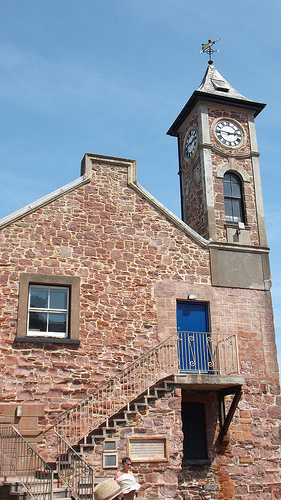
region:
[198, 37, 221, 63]
a lightning rod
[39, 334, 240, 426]
a metal structure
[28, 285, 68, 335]
a white crystal window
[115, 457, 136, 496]
a short hair woman on the scene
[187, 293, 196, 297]
a lamp at the top of the door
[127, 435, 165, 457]
an illegible sign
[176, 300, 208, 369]
a crystal door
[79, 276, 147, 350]
rustic brick wall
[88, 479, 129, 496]
a cream color hat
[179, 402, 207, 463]
a closed window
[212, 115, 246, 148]
clock on the side of the tower.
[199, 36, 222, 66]
Weather vein on the roof.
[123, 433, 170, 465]
Sign on the side of the building.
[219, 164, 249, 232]
window on the building.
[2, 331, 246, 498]
Stairs on the building.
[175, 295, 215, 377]
blue door on the building.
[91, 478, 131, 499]
Tan hat in the forefront.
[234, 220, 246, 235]
Security camera on the window.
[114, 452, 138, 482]
Woman standing by the building.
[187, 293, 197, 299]
Light above the door.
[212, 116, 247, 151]
White and black clock.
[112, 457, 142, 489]
Woman wearing black sunglasses.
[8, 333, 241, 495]
Staircase going up side of building.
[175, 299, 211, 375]
Blue door on side of building.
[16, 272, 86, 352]
Window on side of building.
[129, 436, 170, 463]
Plaque on side of building.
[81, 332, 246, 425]
Metal rail along stairs.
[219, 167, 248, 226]
Window that is rounded on top.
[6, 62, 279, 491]
Red brick historical building.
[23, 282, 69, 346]
Reflection of a tree in window.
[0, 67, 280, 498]
large cobblestone building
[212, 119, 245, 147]
clock on top of cobblestone building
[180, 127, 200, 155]
clock on top of cobblestone building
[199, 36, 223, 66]
weather vane on top of cobblestone builidng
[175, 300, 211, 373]
blue door at upper level of cobblestone building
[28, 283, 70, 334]
window on upper level of cobblestone building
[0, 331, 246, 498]
stairway leading to upper level of cobblestone building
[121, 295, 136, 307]
stone on cobblestone building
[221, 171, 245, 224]
arched window below clock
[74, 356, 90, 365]
stone of the cobblestone building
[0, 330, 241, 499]
Staircase with metal railing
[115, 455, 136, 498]
Older woman wearing pink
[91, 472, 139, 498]
Two light colored hats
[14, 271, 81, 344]
Window in stone framing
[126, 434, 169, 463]
White sign with a border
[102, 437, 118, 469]
Two chalkboards in wood framing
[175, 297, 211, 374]
Single blue door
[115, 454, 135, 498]
Woman wearing sunglasses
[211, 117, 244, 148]
White analog clock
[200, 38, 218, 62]
Metal cross on top of a roof